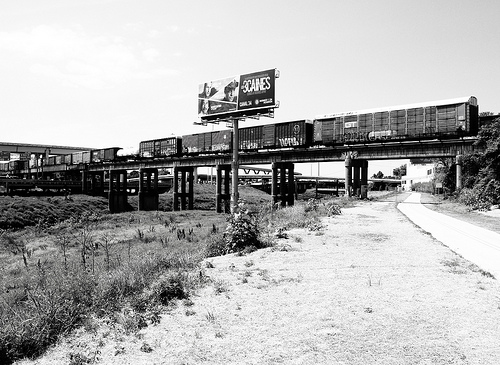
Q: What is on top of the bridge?
A: Train.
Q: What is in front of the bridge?
A: Billboard sign.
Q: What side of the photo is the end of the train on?
A: Right.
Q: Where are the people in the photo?
A: Billboard sign.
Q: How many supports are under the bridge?
A: Six.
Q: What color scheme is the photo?
A: Black and white.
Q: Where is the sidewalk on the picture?
A: Right side.